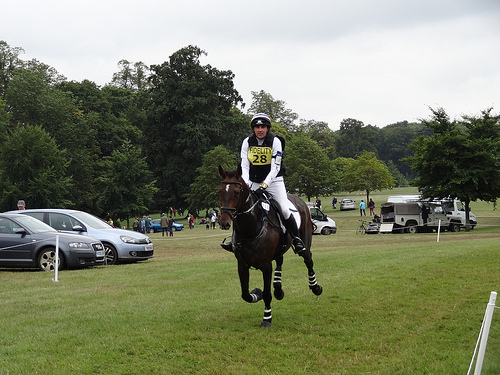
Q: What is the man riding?
A: Horse.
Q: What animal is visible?
A: Horse.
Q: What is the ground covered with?
A: Grass.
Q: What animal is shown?
A: A horse.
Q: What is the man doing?
A: Riding a horse.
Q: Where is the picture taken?
A: A field.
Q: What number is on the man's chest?
A: 28.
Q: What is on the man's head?
A: Helmet.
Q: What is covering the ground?
A: Grass.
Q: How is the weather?
A: Overcast.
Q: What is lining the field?
A: Trees.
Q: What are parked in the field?
A: Cars.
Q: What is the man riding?
A: Horse.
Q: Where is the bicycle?
A: Parked by the white transport van.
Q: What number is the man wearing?
A: 28.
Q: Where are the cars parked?
A: On the grass.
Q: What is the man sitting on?
A: Saddle.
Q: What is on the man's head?
A: Helmet.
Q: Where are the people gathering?
A: At a park.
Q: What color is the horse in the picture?
A: Brown.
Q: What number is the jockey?
A: 28.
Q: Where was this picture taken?
A: At the race track.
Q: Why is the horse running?
A: It's racing.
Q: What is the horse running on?
A: The grass.